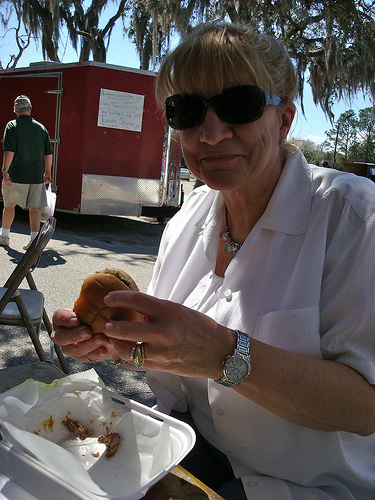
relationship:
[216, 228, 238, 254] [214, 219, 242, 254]
trinket on necklace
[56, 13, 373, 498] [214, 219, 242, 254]
lady wearing a necklace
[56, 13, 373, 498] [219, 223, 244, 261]
lady wearing a necklace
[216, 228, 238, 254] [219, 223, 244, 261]
trinket on necklace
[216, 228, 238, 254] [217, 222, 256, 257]
trinket on necklace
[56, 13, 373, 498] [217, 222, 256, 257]
lady wearing necklace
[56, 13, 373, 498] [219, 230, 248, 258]
lady wearing necklace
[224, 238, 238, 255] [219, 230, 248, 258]
trinket on necklace